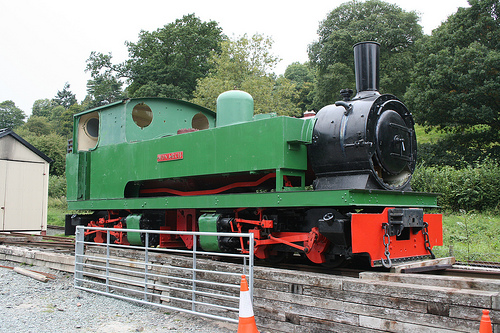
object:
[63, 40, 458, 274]
engine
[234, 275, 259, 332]
cone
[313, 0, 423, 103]
trees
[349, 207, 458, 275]
scoop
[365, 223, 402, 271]
chain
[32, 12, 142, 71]
sky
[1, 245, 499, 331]
plank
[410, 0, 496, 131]
tree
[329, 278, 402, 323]
wall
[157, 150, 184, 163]
label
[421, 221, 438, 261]
chains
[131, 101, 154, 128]
windows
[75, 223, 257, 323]
fence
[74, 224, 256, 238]
rail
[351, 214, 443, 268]
plate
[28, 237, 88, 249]
track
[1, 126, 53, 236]
building